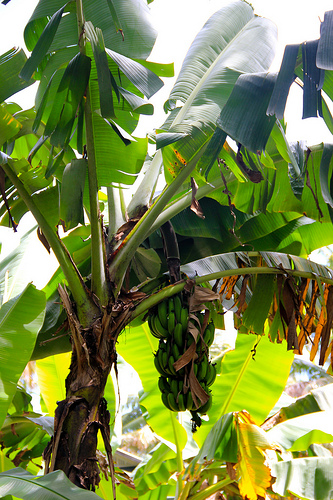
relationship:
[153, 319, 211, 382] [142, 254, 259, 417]
bunch of bananas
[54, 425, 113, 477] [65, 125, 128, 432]
trunk of tree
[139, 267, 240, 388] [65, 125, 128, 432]
banana by tree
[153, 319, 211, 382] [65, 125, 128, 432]
bunch on tree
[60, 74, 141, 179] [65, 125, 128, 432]
leaf on tree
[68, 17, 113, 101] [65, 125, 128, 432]
stem on tree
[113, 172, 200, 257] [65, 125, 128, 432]
branch on tree